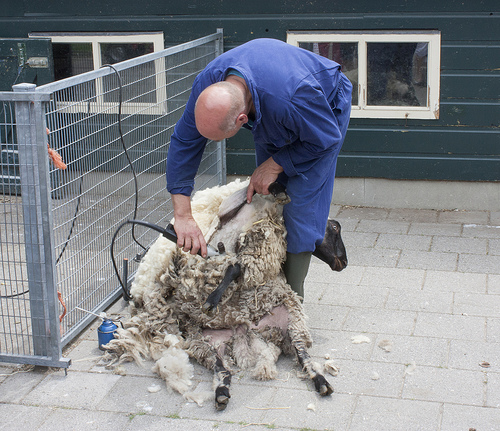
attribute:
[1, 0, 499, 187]
wall — dark , green 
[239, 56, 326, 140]
shearer — dressed in blue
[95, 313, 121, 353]
can — blue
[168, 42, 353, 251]
coat — blue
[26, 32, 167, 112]
window — white, framed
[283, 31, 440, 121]
window — framed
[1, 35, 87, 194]
gate — green 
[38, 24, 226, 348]
fence — gray , metal 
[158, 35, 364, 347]
man — shaving sheep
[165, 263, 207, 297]
wool — shaved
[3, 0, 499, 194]
building — green, white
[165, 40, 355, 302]
man — reflection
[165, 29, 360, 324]
man — bald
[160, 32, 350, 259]
coat — blue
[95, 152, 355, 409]
sheep — black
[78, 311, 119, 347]
oil can — small, blue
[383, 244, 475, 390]
stones — paved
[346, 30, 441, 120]
windows — white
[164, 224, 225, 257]
hair clipper — black, silver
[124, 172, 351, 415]
sheep — fluffy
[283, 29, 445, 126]
window — white, framed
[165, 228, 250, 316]
clippers — industrial sized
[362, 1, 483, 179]
building — green